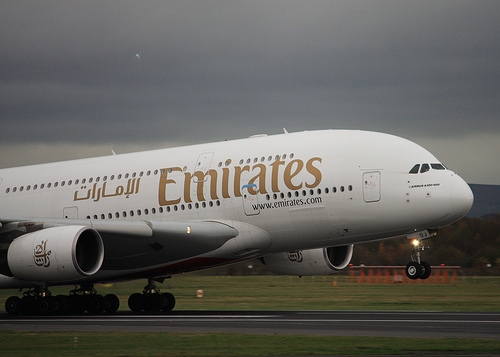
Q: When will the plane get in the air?
A: After it takes off from the ground.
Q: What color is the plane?
A: White and brown.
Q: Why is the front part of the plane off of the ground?
A: Because the plane is getting ready to ascend into the air.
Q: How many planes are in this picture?
A: One.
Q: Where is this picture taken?
A: On an air strip.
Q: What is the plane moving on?
A: A runway.